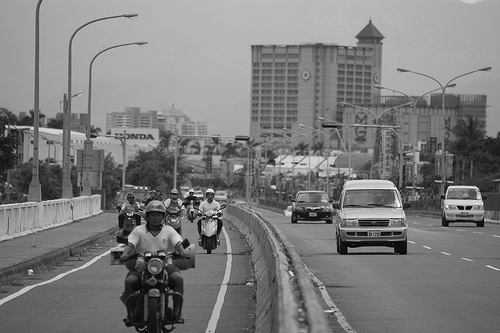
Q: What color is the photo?
A: Black and white.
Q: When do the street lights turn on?
A: At night.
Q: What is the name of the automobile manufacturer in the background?
A: Honda.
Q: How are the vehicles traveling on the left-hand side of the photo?
A: Motorcycle.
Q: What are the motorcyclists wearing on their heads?
A: Helmets.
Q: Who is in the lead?
A: The motorcyclist.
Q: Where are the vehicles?
A: On the highway.